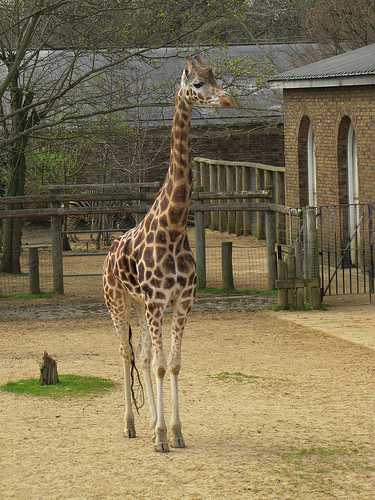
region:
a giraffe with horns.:
[172, 45, 236, 117]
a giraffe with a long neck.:
[158, 98, 198, 200]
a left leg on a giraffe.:
[169, 301, 190, 456]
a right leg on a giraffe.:
[135, 303, 170, 455]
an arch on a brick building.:
[332, 110, 364, 269]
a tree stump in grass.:
[34, 346, 65, 387]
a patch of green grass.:
[0, 346, 124, 400]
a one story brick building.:
[261, 39, 373, 296]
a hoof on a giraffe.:
[171, 423, 193, 448]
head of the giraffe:
[154, 52, 241, 115]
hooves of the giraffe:
[112, 425, 192, 453]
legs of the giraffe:
[108, 330, 198, 430]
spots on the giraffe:
[130, 249, 201, 288]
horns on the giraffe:
[176, 50, 208, 66]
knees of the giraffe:
[148, 357, 181, 374]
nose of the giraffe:
[216, 91, 239, 104]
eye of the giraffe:
[185, 78, 204, 88]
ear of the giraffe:
[175, 66, 191, 78]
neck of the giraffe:
[160, 110, 194, 223]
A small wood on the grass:
[17, 346, 72, 389]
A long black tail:
[126, 325, 149, 412]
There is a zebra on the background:
[61, 185, 130, 243]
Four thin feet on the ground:
[115, 408, 189, 455]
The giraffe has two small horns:
[180, 48, 240, 113]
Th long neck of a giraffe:
[158, 99, 208, 244]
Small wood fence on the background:
[268, 241, 317, 311]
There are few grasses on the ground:
[245, 432, 367, 498]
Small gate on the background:
[307, 196, 372, 304]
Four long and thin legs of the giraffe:
[100, 278, 202, 461]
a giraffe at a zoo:
[88, 43, 260, 469]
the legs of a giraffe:
[100, 308, 215, 464]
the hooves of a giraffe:
[150, 440, 169, 454]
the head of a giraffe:
[172, 49, 241, 116]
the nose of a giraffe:
[219, 89, 235, 102]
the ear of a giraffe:
[179, 64, 190, 83]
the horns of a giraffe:
[182, 48, 199, 68]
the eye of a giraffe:
[190, 78, 206, 93]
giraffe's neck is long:
[157, 103, 210, 248]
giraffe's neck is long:
[156, 104, 185, 248]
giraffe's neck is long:
[153, 110, 209, 266]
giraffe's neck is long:
[156, 96, 207, 276]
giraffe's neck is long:
[162, 108, 192, 232]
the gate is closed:
[311, 198, 374, 290]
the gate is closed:
[308, 201, 374, 322]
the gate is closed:
[311, 197, 367, 311]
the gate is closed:
[306, 185, 372, 319]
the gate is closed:
[313, 192, 374, 305]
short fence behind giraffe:
[207, 225, 287, 308]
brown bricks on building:
[277, 58, 374, 294]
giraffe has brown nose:
[215, 88, 242, 117]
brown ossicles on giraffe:
[183, 49, 211, 76]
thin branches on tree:
[6, 13, 220, 106]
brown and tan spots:
[116, 109, 174, 338]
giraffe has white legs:
[124, 320, 207, 443]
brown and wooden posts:
[184, 162, 288, 282]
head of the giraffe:
[149, 31, 259, 128]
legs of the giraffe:
[89, 328, 227, 424]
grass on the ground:
[62, 367, 116, 415]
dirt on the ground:
[195, 393, 303, 463]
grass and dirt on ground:
[184, 339, 346, 475]